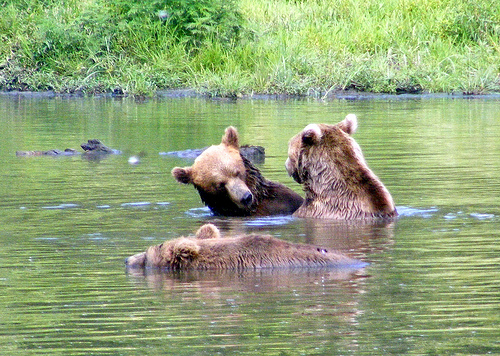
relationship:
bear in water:
[171, 126, 304, 217] [0, 95, 499, 354]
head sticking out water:
[170, 121, 268, 215] [0, 95, 499, 354]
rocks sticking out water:
[12, 138, 264, 160] [0, 95, 499, 354]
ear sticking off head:
[218, 119, 245, 150] [166, 123, 306, 211]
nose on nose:
[240, 190, 255, 207] [240, 190, 252, 207]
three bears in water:
[120, 111, 410, 298] [0, 95, 499, 354]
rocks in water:
[16, 139, 265, 164] [397, 217, 476, 304]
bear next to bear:
[285, 110, 397, 218] [170, 126, 303, 217]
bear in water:
[285, 110, 397, 218] [349, 93, 499, 209]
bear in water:
[170, 126, 303, 217] [349, 93, 499, 209]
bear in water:
[285, 114, 399, 219] [0, 95, 499, 354]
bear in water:
[124, 223, 366, 271] [0, 95, 499, 354]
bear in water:
[285, 110, 397, 218] [0, 95, 499, 354]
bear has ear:
[285, 110, 397, 218] [299, 124, 323, 149]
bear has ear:
[285, 110, 397, 218] [338, 113, 359, 134]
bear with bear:
[124, 223, 366, 271] [285, 110, 397, 218]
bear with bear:
[285, 110, 397, 218] [124, 223, 366, 271]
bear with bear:
[170, 126, 303, 217] [124, 223, 366, 271]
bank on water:
[131, 43, 447, 104] [222, 104, 318, 132]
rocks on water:
[16, 139, 265, 164] [0, 95, 499, 354]